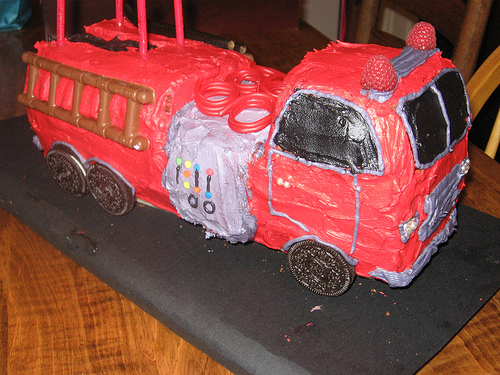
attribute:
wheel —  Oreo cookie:
[287, 240, 351, 297]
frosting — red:
[22, 0, 469, 288]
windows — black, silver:
[278, 69, 472, 188]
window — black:
[264, 89, 396, 181]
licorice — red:
[194, 59, 283, 133]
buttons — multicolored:
[170, 156, 217, 201]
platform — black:
[1, 115, 499, 368]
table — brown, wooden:
[1, 2, 499, 374]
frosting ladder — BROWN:
[15, 47, 153, 154]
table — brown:
[106, 325, 170, 350]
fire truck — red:
[20, 0, 486, 272]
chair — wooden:
[466, 47, 498, 157]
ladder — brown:
[12, 51, 154, 154]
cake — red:
[15, 3, 492, 360]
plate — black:
[0, 167, 495, 359]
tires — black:
[26, 144, 363, 303]